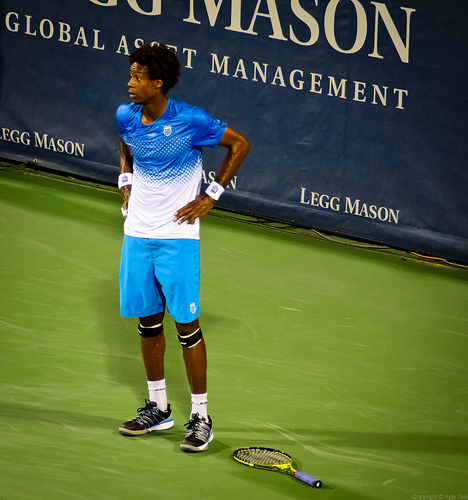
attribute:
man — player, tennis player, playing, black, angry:
[115, 43, 251, 453]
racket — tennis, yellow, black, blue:
[233, 447, 321, 489]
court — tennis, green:
[1, 97, 465, 498]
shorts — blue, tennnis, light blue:
[120, 234, 203, 324]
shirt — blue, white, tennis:
[115, 101, 228, 241]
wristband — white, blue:
[206, 181, 225, 200]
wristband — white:
[118, 172, 134, 189]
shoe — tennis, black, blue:
[180, 413, 214, 453]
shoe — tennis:
[120, 400, 175, 436]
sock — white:
[147, 378, 170, 413]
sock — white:
[189, 392, 212, 427]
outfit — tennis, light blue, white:
[116, 100, 228, 325]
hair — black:
[127, 43, 182, 95]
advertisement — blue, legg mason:
[2, 0, 467, 270]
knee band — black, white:
[137, 324, 165, 338]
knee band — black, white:
[178, 328, 203, 350]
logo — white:
[189, 302, 198, 315]